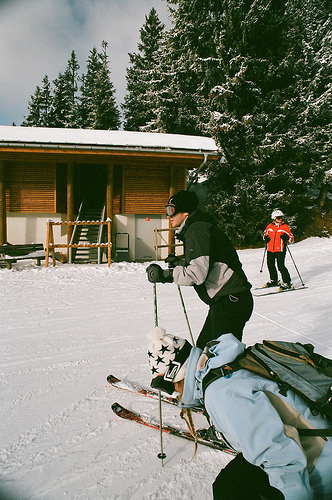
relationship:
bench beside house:
[28, 217, 124, 269] [5, 116, 192, 278]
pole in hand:
[283, 242, 309, 288] [282, 233, 289, 243]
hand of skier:
[282, 233, 289, 243] [260, 209, 293, 293]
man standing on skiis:
[145, 187, 254, 410] [105, 372, 238, 467]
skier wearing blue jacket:
[145, 327, 331, 500] [227, 51, 252, 82]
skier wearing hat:
[145, 327, 331, 500] [148, 324, 189, 382]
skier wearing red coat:
[260, 209, 293, 293] [262, 219, 293, 254]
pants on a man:
[192, 289, 254, 341] [145, 189, 255, 444]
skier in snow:
[258, 210, 304, 292] [16, 274, 99, 398]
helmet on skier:
[270, 206, 282, 225] [256, 222, 307, 297]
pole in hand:
[156, 276, 209, 352] [253, 228, 272, 246]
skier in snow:
[260, 209, 293, 293] [0, 243, 331, 498]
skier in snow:
[147, 330, 330, 498] [0, 243, 331, 498]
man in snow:
[145, 189, 255, 444] [0, 243, 331, 498]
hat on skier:
[144, 328, 193, 384] [147, 330, 330, 498]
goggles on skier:
[145, 375, 177, 399] [131, 322, 329, 488]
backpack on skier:
[197, 325, 330, 426] [138, 312, 331, 498]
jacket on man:
[171, 209, 252, 306] [146, 186, 252, 352]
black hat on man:
[168, 189, 204, 211] [146, 186, 252, 352]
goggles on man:
[164, 202, 178, 217] [146, 186, 252, 352]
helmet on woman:
[262, 199, 283, 224] [262, 197, 300, 304]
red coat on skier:
[262, 221, 294, 253] [260, 209, 293, 293]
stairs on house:
[62, 169, 112, 270] [0, 111, 222, 278]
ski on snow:
[252, 286, 309, 295] [0, 243, 331, 498]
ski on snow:
[109, 400, 230, 461] [0, 243, 331, 498]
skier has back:
[145, 327, 331, 500] [216, 349, 328, 426]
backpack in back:
[224, 336, 330, 417] [216, 349, 328, 426]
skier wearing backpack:
[145, 327, 331, 500] [224, 336, 330, 417]